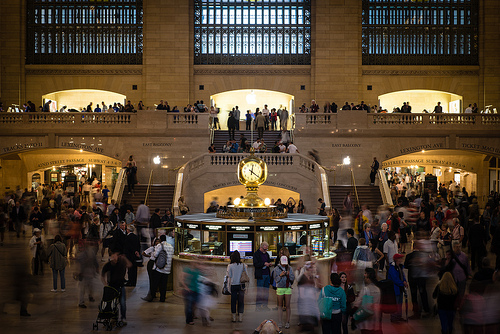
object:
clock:
[238, 157, 266, 183]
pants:
[230, 283, 245, 313]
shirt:
[383, 238, 398, 262]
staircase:
[327, 185, 383, 214]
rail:
[349, 167, 360, 205]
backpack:
[154, 243, 168, 268]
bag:
[239, 264, 250, 282]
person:
[369, 157, 381, 186]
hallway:
[209, 88, 295, 131]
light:
[151, 154, 163, 164]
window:
[28, 0, 143, 66]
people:
[0, 95, 499, 333]